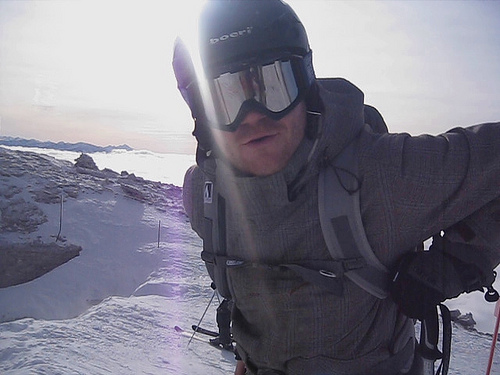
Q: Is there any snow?
A: Yes, there is snow.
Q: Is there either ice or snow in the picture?
A: Yes, there is snow.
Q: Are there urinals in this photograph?
A: No, there are no urinals.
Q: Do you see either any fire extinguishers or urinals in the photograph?
A: No, there are no urinals or fire extinguishers.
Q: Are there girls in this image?
A: No, there are no girls.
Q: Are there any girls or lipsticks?
A: No, there are no girls or lipsticks.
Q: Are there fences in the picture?
A: No, there are no fences.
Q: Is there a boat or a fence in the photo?
A: No, there are no fences or boats.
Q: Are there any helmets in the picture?
A: Yes, there is a helmet.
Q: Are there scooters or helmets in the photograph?
A: Yes, there is a helmet.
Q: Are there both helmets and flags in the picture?
A: No, there is a helmet but no flags.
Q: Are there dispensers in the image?
A: No, there are no dispensers.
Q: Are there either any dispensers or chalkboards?
A: No, there are no dispensers or chalkboards.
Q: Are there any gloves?
A: Yes, there are gloves.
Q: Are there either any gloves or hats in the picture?
A: Yes, there are gloves.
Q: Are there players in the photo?
A: No, there are no players.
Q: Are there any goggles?
A: Yes, there are goggles.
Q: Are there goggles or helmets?
A: Yes, there are goggles.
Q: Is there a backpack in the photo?
A: Yes, there is a backpack.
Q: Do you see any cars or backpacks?
A: Yes, there is a backpack.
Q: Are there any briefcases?
A: No, there are no briefcases.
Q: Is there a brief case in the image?
A: No, there are no briefcases.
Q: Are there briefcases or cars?
A: No, there are no briefcases or cars.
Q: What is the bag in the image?
A: The bag is a backpack.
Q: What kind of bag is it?
A: The bag is a backpack.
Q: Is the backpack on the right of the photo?
A: Yes, the backpack is on the right of the image.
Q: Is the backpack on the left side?
A: No, the backpack is on the right of the image.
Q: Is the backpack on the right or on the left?
A: The backpack is on the right of the image.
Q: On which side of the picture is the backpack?
A: The backpack is on the right of the image.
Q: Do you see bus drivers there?
A: No, there are no bus drivers.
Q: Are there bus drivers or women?
A: No, there are no bus drivers or women.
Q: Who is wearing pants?
A: The man is wearing pants.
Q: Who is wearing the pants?
A: The man is wearing pants.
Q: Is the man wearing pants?
A: Yes, the man is wearing pants.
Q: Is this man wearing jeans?
A: No, the man is wearing pants.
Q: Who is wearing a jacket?
A: The man is wearing a jacket.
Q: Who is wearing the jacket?
A: The man is wearing a jacket.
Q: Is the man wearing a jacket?
A: Yes, the man is wearing a jacket.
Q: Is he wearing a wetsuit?
A: No, the man is wearing a jacket.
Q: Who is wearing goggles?
A: The man is wearing goggles.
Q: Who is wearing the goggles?
A: The man is wearing goggles.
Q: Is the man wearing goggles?
A: Yes, the man is wearing goggles.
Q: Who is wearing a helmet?
A: The man is wearing a helmet.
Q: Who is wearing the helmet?
A: The man is wearing a helmet.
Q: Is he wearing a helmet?
A: Yes, the man is wearing a helmet.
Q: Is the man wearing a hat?
A: No, the man is wearing a helmet.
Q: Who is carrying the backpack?
A: The man is carrying the backpack.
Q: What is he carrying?
A: The man is carrying a backpack.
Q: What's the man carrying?
A: The man is carrying a backpack.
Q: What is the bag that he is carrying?
A: The bag is a backpack.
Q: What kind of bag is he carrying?
A: The man is carrying a backpack.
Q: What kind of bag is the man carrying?
A: The man is carrying a backpack.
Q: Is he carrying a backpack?
A: Yes, the man is carrying a backpack.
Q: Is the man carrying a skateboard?
A: No, the man is carrying a backpack.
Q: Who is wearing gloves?
A: The man is wearing gloves.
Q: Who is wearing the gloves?
A: The man is wearing gloves.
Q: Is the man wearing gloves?
A: Yes, the man is wearing gloves.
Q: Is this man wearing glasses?
A: No, the man is wearing gloves.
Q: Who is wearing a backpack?
A: The man is wearing a backpack.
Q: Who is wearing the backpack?
A: The man is wearing a backpack.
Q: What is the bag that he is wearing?
A: The bag is a backpack.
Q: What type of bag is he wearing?
A: The man is wearing a backpack.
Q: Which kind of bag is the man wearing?
A: The man is wearing a backpack.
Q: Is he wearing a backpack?
A: Yes, the man is wearing a backpack.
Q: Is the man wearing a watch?
A: No, the man is wearing a backpack.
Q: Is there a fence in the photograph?
A: No, there are no fences.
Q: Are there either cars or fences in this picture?
A: No, there are no fences or cars.